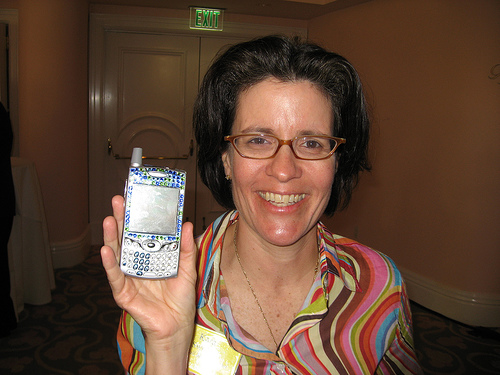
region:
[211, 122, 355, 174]
pair of old fashioned glasses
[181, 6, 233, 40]
bright green exit sign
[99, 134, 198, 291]
bright colorful cell phone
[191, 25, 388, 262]
woman in glasses smiling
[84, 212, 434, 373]
very colorful dress shirt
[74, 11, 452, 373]
woman holding up cell phone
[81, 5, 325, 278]
double doors of conference hall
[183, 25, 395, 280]
woman with short hair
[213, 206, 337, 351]
long gold neck chain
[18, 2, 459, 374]
woman showing off new phone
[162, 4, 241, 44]
The door has an exit sign overhead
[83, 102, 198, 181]
The door has a panic bar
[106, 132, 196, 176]
The panic bar is gold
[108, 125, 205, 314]
The woman is holding a cell phone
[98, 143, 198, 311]
The woman's cell phone is on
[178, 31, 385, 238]
The woman has dark hair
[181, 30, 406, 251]
The woman's hair is black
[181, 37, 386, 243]
The woman's hair is straight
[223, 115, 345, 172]
The woman is wearing corrective lenses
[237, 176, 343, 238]
The woman is smiling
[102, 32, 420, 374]
Woman wearing striped shirt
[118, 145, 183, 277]
Cellphone in the woman's hand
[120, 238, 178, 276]
Buttons on the cellphone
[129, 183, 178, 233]
Screen on the cellphone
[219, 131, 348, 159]
Glasses on the woman's face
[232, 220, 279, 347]
Necklace on the woman's neck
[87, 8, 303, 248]
White doors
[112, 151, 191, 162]
Handle on the door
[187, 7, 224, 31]
Exit sign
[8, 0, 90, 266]
Pillar next to the door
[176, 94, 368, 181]
the lady is wearing glasses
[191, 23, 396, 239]
the lady looks happy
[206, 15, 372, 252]
she is smiling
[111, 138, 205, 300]
this is her cell phone?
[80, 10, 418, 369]
she obviously likes bright colors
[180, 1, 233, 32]
the sign says exit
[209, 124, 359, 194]
the lady has brown eyes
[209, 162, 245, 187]
she is wearing earrings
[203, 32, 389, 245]
she has very dark hair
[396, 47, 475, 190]
the wall appears to be a peach color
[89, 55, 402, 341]
Woman holding a cellphone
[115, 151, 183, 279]
The cellphone is covered in rhinestones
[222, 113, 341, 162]
The woman is wearing glasses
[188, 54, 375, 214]
Her hair is dark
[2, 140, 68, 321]
A coat is hanging on the door knob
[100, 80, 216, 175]
The door handle is on the door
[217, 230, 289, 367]
Gold chain on woman's neck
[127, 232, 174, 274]
The phone has a keyboard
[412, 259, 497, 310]
Bottom of the wall has paneling on it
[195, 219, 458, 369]
The woman's shirt is colorful